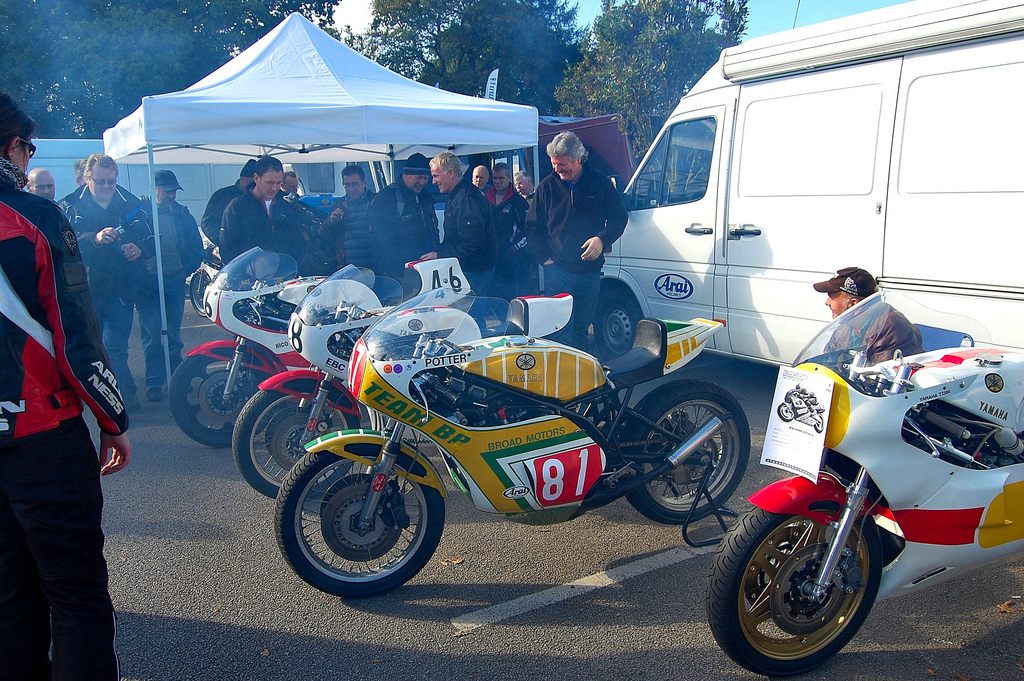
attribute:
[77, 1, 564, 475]
tent — white, cloth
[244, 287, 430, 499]
motorcycle — red, white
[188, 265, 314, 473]
motorcycle — red, white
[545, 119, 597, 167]
hair — light colored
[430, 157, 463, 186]
hair — light colored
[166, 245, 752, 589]
three motorcycles — standing in a row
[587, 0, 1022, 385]
van — white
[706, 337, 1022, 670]
bike — separate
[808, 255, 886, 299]
cap — black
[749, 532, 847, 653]
rim — gold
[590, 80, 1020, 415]
van — white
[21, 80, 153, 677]
jacket — white, red, blue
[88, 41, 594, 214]
canopy — white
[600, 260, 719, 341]
oval — blue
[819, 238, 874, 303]
cap — dark brown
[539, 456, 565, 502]
number — white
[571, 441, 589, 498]
number — white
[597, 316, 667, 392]
seat — black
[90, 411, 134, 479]
person's hand — pictured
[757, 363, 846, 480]
paper — white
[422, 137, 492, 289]
man — standing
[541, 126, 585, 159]
hair — grey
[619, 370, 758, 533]
back wheel — black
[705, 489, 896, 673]
front wheel — black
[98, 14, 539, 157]
tent — white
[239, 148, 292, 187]
hair — dark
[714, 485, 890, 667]
wheel — black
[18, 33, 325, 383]
smoke — blowing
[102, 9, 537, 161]
canopy — white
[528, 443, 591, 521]
numbers — white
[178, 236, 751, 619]
bikes — lined-up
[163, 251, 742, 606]
bikes — alongside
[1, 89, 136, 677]
guy — red, black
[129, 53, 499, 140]
canopy — white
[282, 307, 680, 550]
motor bike — yellow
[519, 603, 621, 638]
stripe — white